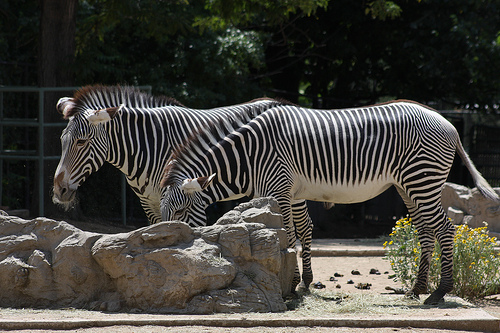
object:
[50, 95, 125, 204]
head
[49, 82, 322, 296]
zebra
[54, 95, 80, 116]
ears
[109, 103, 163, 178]
neck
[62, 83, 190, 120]
main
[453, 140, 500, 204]
tail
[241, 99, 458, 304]
body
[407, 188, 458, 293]
legs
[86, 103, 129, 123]
ear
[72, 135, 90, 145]
eye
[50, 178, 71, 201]
nose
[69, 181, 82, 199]
jaw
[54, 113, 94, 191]
zebra's face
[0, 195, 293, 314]
outcropping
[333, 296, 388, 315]
patch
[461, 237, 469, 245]
flowers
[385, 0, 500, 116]
trees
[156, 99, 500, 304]
zebra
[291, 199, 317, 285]
leg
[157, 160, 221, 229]
head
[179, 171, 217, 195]
ear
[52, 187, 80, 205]
mouth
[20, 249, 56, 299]
rock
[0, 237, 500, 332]
ground